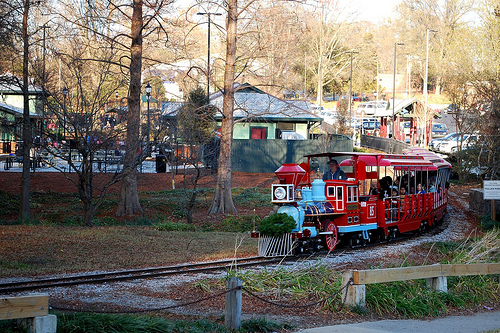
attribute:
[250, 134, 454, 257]
train — here, red, turning, white, long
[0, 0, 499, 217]
tree — brown, bare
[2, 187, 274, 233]
grass — here, green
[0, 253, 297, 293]
tracks — rusty, here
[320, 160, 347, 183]
guard — driving, here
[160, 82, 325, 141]
house — green, here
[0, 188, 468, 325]
rocks — here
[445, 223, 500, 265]
weeds — here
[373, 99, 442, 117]
roof — brown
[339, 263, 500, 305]
fence — long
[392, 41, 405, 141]
pole — short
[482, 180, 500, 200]
sign — white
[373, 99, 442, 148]
tram — here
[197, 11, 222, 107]
lamp post — black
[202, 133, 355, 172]
fence — green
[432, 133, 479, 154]
cars — parked, here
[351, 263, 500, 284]
railing — wooden